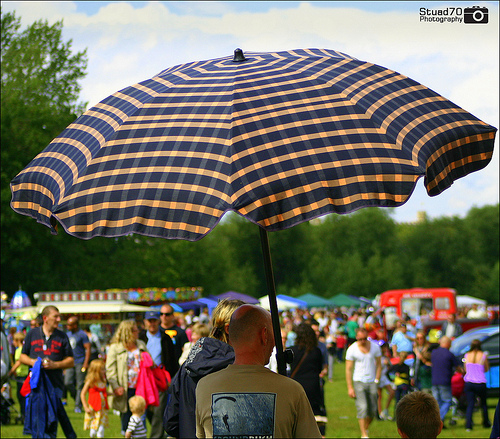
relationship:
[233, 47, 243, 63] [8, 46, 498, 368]
knob on umbrella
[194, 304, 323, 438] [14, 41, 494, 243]
man holding umbrella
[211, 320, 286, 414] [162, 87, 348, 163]
man holding umbrella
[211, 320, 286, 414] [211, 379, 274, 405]
man wearing t-shirt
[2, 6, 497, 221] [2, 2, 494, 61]
clouds in sky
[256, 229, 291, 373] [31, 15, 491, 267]
handle of umbrella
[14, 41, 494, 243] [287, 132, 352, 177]
umbrella with dots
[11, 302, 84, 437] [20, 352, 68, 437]
man carrying jacket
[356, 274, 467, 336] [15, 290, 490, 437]
bus near crowd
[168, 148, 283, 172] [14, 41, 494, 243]
dots on umbrella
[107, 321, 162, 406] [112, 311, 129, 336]
woman with hair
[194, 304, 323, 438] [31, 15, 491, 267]
man holding umbrella